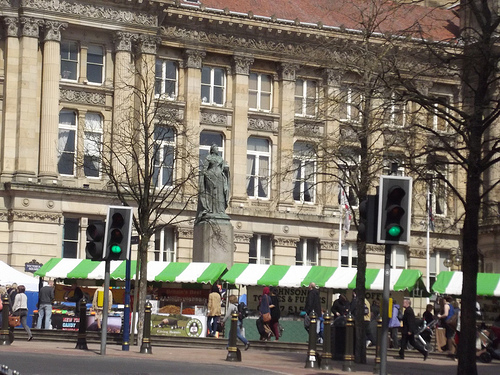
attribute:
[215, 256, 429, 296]
roof — white, green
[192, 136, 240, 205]
statue — concrete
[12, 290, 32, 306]
shirt — white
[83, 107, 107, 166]
curtain — white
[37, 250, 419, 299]
awning — white, green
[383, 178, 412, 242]
traffic lights — black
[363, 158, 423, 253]
frame — white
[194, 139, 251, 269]
statue — tall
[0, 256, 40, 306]
awning — white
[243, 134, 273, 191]
curtains — white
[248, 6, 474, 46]
roof — red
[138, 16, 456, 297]
building — tan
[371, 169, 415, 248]
traffic light — green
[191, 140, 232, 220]
statue — LADY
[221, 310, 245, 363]
pole — BLACK, METAL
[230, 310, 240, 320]
trim — GOLD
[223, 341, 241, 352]
trim — GOLD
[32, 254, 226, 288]
awning — WHITE, GREEN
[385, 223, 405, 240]
light — GREEN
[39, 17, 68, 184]
column — ORNATE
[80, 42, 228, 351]
tree — LEAFLESS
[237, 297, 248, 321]
backpack — BLACK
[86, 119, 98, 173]
curtain — WHITE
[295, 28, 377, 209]
leaves — DRY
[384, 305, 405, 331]
coat — purple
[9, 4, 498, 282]
building — large